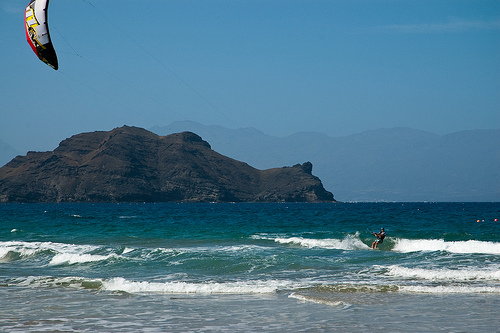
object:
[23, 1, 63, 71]
parafoil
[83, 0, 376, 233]
cables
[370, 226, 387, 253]
man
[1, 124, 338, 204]
mountain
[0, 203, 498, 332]
water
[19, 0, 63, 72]
object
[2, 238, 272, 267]
sea foam